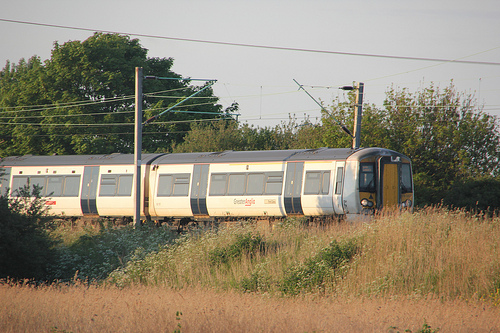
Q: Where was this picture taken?
A: Near a train track.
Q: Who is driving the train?
A: The conductor.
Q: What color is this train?
A: Gray and black.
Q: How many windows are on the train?
A: 17.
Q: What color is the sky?
A: It's cloudy.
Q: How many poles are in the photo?
A: 2.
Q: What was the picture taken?
A: Daytime.